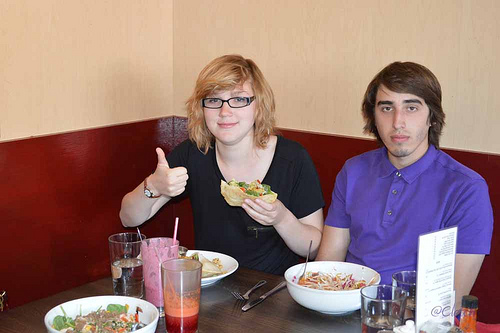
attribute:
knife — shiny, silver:
[240, 281, 286, 317]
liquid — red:
[169, 313, 189, 331]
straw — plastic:
[168, 210, 185, 236]